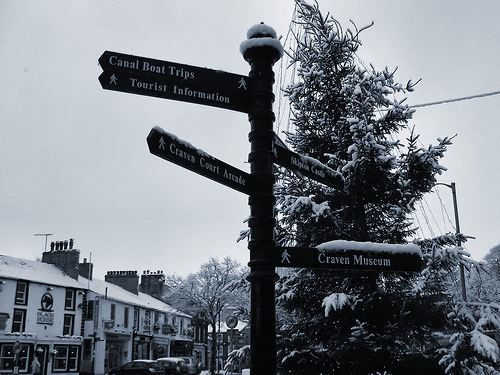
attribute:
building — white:
[84, 267, 143, 372]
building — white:
[3, 243, 88, 364]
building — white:
[146, 282, 205, 372]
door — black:
[32, 343, 49, 373]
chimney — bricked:
[42, 227, 88, 272]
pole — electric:
[425, 157, 479, 342]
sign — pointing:
[90, 50, 256, 117]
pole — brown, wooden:
[239, 18, 290, 373]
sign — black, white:
[92, 44, 258, 115]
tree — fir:
[248, 0, 460, 351]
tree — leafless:
[288, 16, 457, 373]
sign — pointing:
[271, 140, 346, 190]